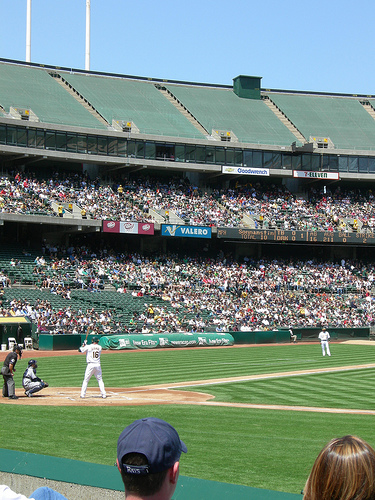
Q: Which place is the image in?
A: It is at the stadium.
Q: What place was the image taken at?
A: It was taken at the stadium.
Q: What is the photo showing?
A: It is showing a stadium.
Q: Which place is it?
A: It is a stadium.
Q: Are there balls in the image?
A: No, there are no balls.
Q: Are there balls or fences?
A: No, there are no balls or fences.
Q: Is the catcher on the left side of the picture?
A: Yes, the catcher is on the left of the image.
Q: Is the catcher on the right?
A: No, the catcher is on the left of the image.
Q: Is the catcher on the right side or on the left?
A: The catcher is on the left of the image.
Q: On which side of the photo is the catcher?
A: The catcher is on the left of the image.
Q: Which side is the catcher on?
A: The catcher is on the left of the image.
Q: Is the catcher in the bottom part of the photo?
A: Yes, the catcher is in the bottom of the image.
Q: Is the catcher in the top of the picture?
A: No, the catcher is in the bottom of the image.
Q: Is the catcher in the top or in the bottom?
A: The catcher is in the bottom of the image.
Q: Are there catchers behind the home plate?
A: Yes, there is a catcher behind the home plate.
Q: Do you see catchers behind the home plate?
A: Yes, there is a catcher behind the home plate.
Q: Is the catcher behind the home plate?
A: Yes, the catcher is behind the home plate.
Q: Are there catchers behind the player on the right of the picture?
A: Yes, there is a catcher behind the player.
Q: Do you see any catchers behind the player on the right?
A: Yes, there is a catcher behind the player.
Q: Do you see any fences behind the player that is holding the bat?
A: No, there is a catcher behind the player.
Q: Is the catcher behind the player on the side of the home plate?
A: Yes, the catcher is behind the player.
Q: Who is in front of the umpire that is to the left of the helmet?
A: The catcher is in front of the umpire.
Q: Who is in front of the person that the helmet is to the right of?
A: The catcher is in front of the umpire.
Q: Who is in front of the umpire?
A: The catcher is in front of the umpire.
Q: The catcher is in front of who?
A: The catcher is in front of the umpire.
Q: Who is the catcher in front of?
A: The catcher is in front of the umpire.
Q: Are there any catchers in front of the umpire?
A: Yes, there is a catcher in front of the umpire.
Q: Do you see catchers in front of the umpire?
A: Yes, there is a catcher in front of the umpire.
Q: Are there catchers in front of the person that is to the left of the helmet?
A: Yes, there is a catcher in front of the umpire.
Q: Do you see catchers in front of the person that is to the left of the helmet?
A: Yes, there is a catcher in front of the umpire.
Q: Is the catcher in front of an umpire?
A: Yes, the catcher is in front of an umpire.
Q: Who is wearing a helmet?
A: The catcher is wearing a helmet.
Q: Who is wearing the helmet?
A: The catcher is wearing a helmet.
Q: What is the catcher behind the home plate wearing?
A: The catcher is wearing a helmet.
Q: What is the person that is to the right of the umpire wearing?
A: The catcher is wearing a helmet.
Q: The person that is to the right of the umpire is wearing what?
A: The catcher is wearing a helmet.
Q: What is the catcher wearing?
A: The catcher is wearing a helmet.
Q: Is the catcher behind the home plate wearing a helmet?
A: Yes, the catcher is wearing a helmet.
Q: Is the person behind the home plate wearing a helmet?
A: Yes, the catcher is wearing a helmet.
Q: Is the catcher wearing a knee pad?
A: No, the catcher is wearing a helmet.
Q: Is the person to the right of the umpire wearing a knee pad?
A: No, the catcher is wearing a helmet.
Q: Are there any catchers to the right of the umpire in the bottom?
A: Yes, there is a catcher to the right of the umpire.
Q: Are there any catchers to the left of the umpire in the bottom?
A: No, the catcher is to the right of the umpire.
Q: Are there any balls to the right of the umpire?
A: No, there is a catcher to the right of the umpire.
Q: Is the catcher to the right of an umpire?
A: Yes, the catcher is to the right of an umpire.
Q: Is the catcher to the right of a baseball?
A: No, the catcher is to the right of an umpire.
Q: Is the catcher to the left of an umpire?
A: No, the catcher is to the right of an umpire.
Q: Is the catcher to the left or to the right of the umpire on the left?
A: The catcher is to the right of the umpire.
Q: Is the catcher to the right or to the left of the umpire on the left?
A: The catcher is to the right of the umpire.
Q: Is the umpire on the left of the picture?
A: Yes, the umpire is on the left of the image.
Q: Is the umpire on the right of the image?
A: No, the umpire is on the left of the image.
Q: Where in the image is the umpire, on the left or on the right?
A: The umpire is on the left of the image.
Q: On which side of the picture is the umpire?
A: The umpire is on the left of the image.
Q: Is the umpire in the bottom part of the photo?
A: Yes, the umpire is in the bottom of the image.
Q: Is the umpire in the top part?
A: No, the umpire is in the bottom of the image.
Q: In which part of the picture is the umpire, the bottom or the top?
A: The umpire is in the bottom of the image.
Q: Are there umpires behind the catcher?
A: Yes, there is an umpire behind the catcher.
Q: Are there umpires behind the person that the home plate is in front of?
A: Yes, there is an umpire behind the catcher.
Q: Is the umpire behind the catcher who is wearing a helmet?
A: Yes, the umpire is behind the catcher.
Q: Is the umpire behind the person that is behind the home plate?
A: Yes, the umpire is behind the catcher.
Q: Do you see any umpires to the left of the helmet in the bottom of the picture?
A: Yes, there is an umpire to the left of the helmet.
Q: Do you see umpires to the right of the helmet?
A: No, the umpire is to the left of the helmet.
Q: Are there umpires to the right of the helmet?
A: No, the umpire is to the left of the helmet.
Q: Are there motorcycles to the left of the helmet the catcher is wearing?
A: No, there is an umpire to the left of the helmet.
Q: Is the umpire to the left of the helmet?
A: Yes, the umpire is to the left of the helmet.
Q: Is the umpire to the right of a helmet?
A: No, the umpire is to the left of a helmet.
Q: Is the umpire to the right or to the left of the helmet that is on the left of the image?
A: The umpire is to the left of the helmet.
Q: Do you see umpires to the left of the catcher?
A: Yes, there is an umpire to the left of the catcher.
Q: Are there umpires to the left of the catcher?
A: Yes, there is an umpire to the left of the catcher.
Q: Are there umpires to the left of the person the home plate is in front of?
A: Yes, there is an umpire to the left of the catcher.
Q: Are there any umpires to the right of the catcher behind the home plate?
A: No, the umpire is to the left of the catcher.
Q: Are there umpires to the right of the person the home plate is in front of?
A: No, the umpire is to the left of the catcher.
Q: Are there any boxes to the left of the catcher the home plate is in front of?
A: No, there is an umpire to the left of the catcher.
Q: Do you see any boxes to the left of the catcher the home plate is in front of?
A: No, there is an umpire to the left of the catcher.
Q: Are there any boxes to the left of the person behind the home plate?
A: No, there is an umpire to the left of the catcher.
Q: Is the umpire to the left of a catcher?
A: Yes, the umpire is to the left of a catcher.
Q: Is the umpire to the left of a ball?
A: No, the umpire is to the left of a catcher.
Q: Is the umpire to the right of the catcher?
A: No, the umpire is to the left of the catcher.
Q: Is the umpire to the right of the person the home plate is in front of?
A: No, the umpire is to the left of the catcher.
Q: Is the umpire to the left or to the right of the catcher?
A: The umpire is to the left of the catcher.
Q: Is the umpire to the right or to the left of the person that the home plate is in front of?
A: The umpire is to the left of the catcher.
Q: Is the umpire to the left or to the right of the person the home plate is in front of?
A: The umpire is to the left of the catcher.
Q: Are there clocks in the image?
A: No, there are no clocks.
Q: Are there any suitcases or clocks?
A: No, there are no clocks or suitcases.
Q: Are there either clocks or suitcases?
A: No, there are no clocks or suitcases.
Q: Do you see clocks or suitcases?
A: No, there are no clocks or suitcases.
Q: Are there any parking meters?
A: No, there are no parking meters.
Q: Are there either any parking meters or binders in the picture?
A: No, there are no parking meters or binders.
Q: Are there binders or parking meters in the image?
A: No, there are no parking meters or binders.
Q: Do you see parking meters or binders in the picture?
A: No, there are no parking meters or binders.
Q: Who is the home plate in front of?
A: The home plate is in front of the catcher.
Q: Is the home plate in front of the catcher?
A: Yes, the home plate is in front of the catcher.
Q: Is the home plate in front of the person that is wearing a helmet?
A: Yes, the home plate is in front of the catcher.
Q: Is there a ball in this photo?
A: No, there are no balls.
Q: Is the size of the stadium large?
A: Yes, the stadium is large.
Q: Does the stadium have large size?
A: Yes, the stadium is large.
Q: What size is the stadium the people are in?
A: The stadium is large.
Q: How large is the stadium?
A: The stadium is large.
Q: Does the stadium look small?
A: No, the stadium is large.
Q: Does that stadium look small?
A: No, the stadium is large.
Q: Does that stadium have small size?
A: No, the stadium is large.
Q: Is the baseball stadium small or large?
A: The stadium is large.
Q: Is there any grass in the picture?
A: Yes, there is grass.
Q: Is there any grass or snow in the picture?
A: Yes, there is grass.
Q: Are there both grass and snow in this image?
A: No, there is grass but no snow.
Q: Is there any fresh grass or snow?
A: Yes, there is fresh grass.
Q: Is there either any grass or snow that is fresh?
A: Yes, the grass is fresh.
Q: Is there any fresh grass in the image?
A: Yes, there is fresh grass.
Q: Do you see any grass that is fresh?
A: Yes, there is grass that is fresh.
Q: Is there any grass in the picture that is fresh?
A: Yes, there is grass that is fresh.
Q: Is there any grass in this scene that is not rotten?
A: Yes, there is fresh grass.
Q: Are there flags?
A: No, there are no flags.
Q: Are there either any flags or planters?
A: No, there are no flags or planters.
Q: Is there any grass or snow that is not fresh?
A: No, there is grass but it is fresh.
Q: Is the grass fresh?
A: Yes, the grass is fresh.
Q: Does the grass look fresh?
A: Yes, the grass is fresh.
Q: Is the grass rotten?
A: No, the grass is fresh.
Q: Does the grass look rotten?
A: No, the grass is fresh.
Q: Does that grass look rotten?
A: No, the grass is fresh.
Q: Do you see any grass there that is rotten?
A: No, there is grass but it is fresh.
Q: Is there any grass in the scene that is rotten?
A: No, there is grass but it is fresh.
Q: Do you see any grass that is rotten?
A: No, there is grass but it is fresh.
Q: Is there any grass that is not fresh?
A: No, there is grass but it is fresh.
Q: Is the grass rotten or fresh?
A: The grass is fresh.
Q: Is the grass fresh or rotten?
A: The grass is fresh.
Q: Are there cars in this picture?
A: No, there are no cars.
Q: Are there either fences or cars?
A: No, there are no cars or fences.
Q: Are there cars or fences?
A: No, there are no cars or fences.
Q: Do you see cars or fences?
A: No, there are no cars or fences.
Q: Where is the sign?
A: The sign is in the stadium.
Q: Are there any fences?
A: No, there are no fences.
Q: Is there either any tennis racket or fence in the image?
A: No, there are no fences or rackets.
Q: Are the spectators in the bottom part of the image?
A: Yes, the spectators are in the bottom of the image.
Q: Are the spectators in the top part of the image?
A: No, the spectators are in the bottom of the image.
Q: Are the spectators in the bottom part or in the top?
A: The spectators are in the bottom of the image.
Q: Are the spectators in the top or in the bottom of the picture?
A: The spectators are in the bottom of the image.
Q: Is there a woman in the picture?
A: Yes, there is a woman.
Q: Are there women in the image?
A: Yes, there is a woman.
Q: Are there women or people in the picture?
A: Yes, there is a woman.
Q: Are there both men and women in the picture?
A: Yes, there are both a woman and a man.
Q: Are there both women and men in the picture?
A: Yes, there are both a woman and a man.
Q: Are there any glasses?
A: No, there are no glasses.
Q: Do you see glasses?
A: No, there are no glasses.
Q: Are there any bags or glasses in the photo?
A: No, there are no glasses or bags.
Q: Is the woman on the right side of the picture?
A: Yes, the woman is on the right of the image.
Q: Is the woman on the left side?
A: No, the woman is on the right of the image.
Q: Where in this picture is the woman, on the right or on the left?
A: The woman is on the right of the image.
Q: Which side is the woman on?
A: The woman is on the right of the image.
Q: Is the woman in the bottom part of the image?
A: Yes, the woman is in the bottom of the image.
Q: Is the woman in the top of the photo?
A: No, the woman is in the bottom of the image.